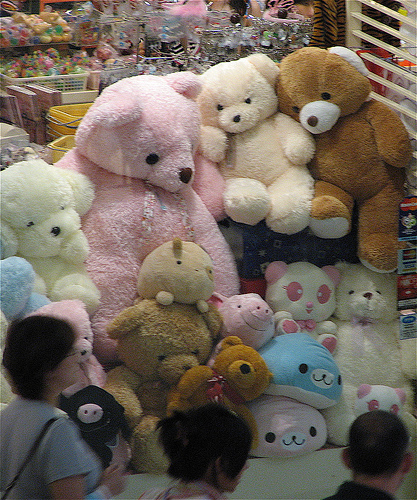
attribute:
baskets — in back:
[47, 103, 92, 163]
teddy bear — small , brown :
[103, 296, 223, 477]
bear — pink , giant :
[45, 53, 280, 363]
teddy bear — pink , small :
[22, 297, 103, 406]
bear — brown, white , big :
[277, 46, 412, 272]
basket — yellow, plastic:
[48, 132, 75, 159]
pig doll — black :
[59, 385, 134, 472]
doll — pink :
[199, 280, 282, 353]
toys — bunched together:
[198, 69, 324, 224]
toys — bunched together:
[291, 51, 416, 244]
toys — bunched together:
[84, 90, 238, 324]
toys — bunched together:
[2, 156, 119, 322]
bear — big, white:
[184, 62, 316, 225]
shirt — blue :
[1, 398, 102, 496]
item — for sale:
[69, 6, 101, 47]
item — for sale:
[308, 2, 346, 50]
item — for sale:
[0, 70, 88, 90]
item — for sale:
[229, 14, 242, 24]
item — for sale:
[142, 12, 182, 40]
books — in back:
[2, 82, 62, 142]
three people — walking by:
[55, 344, 414, 435]